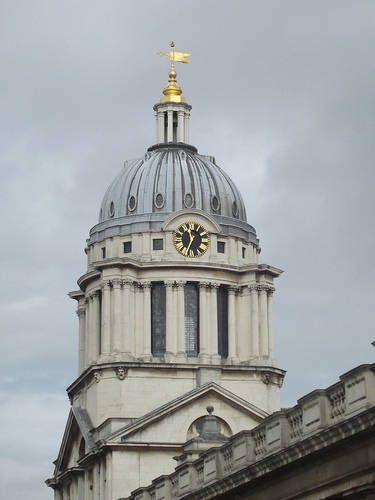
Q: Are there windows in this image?
A: Yes, there is a window.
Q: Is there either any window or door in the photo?
A: Yes, there is a window.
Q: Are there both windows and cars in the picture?
A: No, there is a window but no cars.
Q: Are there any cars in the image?
A: No, there are no cars.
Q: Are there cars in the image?
A: No, there are no cars.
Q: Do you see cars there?
A: No, there are no cars.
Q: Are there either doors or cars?
A: No, there are no cars or doors.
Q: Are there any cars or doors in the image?
A: No, there are no cars or doors.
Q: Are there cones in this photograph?
A: No, there are no cones.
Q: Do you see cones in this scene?
A: No, there are no cones.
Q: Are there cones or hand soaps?
A: No, there are no cones or hand soaps.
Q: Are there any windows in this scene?
A: Yes, there are windows.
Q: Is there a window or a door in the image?
A: Yes, there are windows.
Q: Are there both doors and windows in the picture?
A: No, there are windows but no doors.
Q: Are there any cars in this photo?
A: No, there are no cars.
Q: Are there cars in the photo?
A: No, there are no cars.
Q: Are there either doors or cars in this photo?
A: No, there are no cars or doors.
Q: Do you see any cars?
A: No, there are no cars.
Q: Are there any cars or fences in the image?
A: No, there are no cars or fences.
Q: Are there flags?
A: Yes, there is a flag.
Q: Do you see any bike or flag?
A: Yes, there is a flag.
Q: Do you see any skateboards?
A: No, there are no skateboards.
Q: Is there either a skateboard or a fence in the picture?
A: No, there are no skateboards or fences.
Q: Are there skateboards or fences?
A: No, there are no skateboards or fences.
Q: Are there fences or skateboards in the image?
A: No, there are no skateboards or fences.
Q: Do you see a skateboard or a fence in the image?
A: No, there are no skateboards or fences.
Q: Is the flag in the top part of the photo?
A: Yes, the flag is in the top of the image.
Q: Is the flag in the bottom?
A: No, the flag is in the top of the image.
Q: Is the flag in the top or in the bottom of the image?
A: The flag is in the top of the image.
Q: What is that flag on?
A: The flag is on the tower.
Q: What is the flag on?
A: The flag is on the tower.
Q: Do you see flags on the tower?
A: Yes, there is a flag on the tower.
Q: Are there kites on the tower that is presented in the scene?
A: No, there is a flag on the tower.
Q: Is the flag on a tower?
A: Yes, the flag is on a tower.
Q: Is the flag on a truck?
A: No, the flag is on a tower.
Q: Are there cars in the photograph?
A: No, there are no cars.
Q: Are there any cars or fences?
A: No, there are no cars or fences.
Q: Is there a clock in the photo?
A: Yes, there is a clock.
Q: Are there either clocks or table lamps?
A: Yes, there is a clock.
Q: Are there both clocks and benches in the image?
A: No, there is a clock but no benches.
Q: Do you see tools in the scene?
A: No, there are no tools.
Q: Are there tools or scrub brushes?
A: No, there are no tools or scrub brushes.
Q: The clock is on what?
A: The clock is on the tower.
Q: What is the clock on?
A: The clock is on the tower.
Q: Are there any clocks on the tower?
A: Yes, there is a clock on the tower.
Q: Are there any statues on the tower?
A: No, there is a clock on the tower.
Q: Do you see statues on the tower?
A: No, there is a clock on the tower.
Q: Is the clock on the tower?
A: Yes, the clock is on the tower.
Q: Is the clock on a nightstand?
A: No, the clock is on the tower.